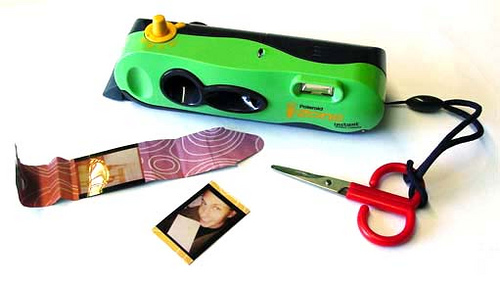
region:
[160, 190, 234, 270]
Picture of a man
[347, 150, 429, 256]
Red color of scissor handles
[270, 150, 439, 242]
Small red pair of scissors.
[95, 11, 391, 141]
New green colored polaroid camera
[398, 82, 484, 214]
String attaching scissors to polaroid camera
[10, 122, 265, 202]
New polaroid strip with picture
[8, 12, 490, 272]
Polaroid camera set up for pictures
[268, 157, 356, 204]
Steel tip of small scissors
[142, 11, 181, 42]
Button to take a picture on camera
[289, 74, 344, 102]
Polaroid flash on camera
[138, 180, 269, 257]
A photo of someone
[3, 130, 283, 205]
A film roll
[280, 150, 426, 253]
a small pair of scissors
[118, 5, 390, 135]
a green and black camera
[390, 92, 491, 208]
a strap on the camera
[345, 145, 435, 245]
the red handle of the scissors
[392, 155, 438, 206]
the strap tied to the handle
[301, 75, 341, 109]
the flash of the camera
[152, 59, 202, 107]
the lens of the camera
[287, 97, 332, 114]
branding on the camera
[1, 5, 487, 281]
a polaroid camera and accesories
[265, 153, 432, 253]
small red scissors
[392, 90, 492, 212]
black wrist strap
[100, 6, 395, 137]
green and black Polaroid camera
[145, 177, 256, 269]
a finished photo of a person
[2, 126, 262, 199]
a developing photo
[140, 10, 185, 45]
the yellow camera button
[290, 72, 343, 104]
the camera's flash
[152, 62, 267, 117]
the camera's lens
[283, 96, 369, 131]
the company logo under the flash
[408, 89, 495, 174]
a fabric rope handle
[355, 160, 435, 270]
rounded red plastic scissor handles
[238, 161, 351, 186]
blades of the scissors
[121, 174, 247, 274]
picture taken by camera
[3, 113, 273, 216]
film from a camera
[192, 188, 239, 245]
face on the picture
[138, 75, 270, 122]
lens on the camera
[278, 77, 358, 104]
clear light of flashbulb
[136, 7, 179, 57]
Button to trigger picture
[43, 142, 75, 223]
wrinkle in the film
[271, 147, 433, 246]
A red handled scissors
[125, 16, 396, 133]
A green polaroid instant camera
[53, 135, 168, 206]
Possibly damaged film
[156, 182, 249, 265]
A properly developed instant photgraph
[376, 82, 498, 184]
A lanyard connecting scissors to camera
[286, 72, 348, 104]
An apparatus to create flash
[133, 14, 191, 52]
A selector switch to change camera modes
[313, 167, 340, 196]
A screw with which to tighten the scissors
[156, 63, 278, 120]
The cameras lens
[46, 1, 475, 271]
Someones travel camera kit